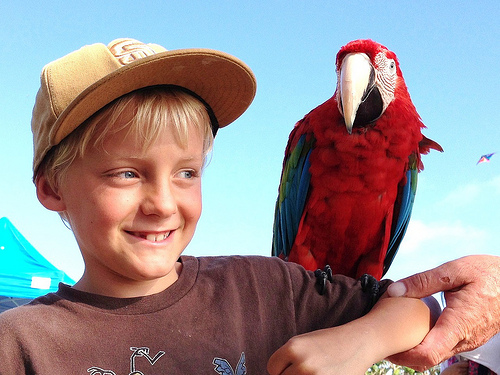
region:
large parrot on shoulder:
[260, 41, 437, 271]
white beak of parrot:
[338, 52, 369, 136]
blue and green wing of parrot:
[371, 156, 422, 270]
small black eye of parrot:
[387, 51, 399, 75]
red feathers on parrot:
[280, 49, 435, 261]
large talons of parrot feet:
[314, 265, 341, 293]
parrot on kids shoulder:
[0, 29, 465, 371]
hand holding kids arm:
[391, 258, 493, 373]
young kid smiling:
[20, 106, 218, 301]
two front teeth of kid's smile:
[144, 223, 176, 248]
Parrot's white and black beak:
[327, 49, 375, 131]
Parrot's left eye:
[382, 58, 399, 75]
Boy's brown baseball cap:
[16, 35, 263, 184]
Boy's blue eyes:
[95, 158, 206, 193]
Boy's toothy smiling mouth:
[103, 216, 199, 257]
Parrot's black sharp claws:
[294, 256, 386, 303]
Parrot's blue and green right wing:
[265, 130, 321, 277]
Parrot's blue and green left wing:
[372, 149, 422, 274]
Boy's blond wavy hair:
[23, 87, 235, 196]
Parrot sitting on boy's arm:
[265, 33, 452, 293]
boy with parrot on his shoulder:
[11, 27, 453, 374]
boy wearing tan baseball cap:
[0, 6, 491, 363]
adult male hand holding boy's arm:
[0, 10, 492, 372]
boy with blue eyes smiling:
[12, 45, 227, 374]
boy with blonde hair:
[23, 18, 263, 373]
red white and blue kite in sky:
[463, 95, 496, 197]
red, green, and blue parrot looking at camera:
[1, 13, 458, 371]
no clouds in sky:
[7, 5, 487, 263]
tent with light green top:
[0, 203, 81, 336]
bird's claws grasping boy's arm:
[258, 9, 434, 342]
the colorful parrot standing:
[271, 36, 449, 291]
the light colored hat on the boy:
[31, 33, 256, 177]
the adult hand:
[391, 252, 498, 369]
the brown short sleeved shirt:
[6, 258, 386, 374]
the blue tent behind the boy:
[1, 213, 81, 300]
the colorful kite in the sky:
[476, 150, 496, 165]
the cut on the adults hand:
[439, 275, 449, 287]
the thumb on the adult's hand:
[387, 263, 464, 298]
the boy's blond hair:
[43, 90, 220, 150]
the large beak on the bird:
[332, 52, 369, 132]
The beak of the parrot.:
[338, 52, 370, 133]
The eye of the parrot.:
[390, 53, 398, 78]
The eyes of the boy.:
[99, 160, 208, 195]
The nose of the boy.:
[141, 190, 187, 220]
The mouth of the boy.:
[120, 226, 186, 247]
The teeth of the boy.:
[140, 228, 172, 243]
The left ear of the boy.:
[38, 161, 62, 211]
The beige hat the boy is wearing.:
[11, 43, 259, 154]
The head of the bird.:
[319, 36, 398, 130]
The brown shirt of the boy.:
[0, 260, 349, 372]